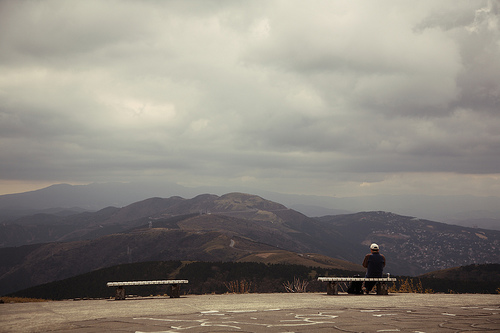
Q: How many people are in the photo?
A: One.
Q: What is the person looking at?
A: Probably the sky.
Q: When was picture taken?
A: During the day.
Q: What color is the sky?
A: Grey.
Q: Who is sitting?
A: A person.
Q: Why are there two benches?
A: Tourist site.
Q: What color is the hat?
A: White.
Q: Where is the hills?
A: Background.